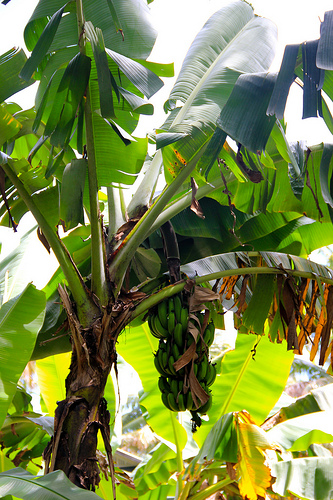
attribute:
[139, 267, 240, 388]
banana — hanging, bunch, here, bunched, bundled, present, unripe, stok, stock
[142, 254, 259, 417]
bananas — ripening, hanging, bunch, unripe, here, ready, green, growing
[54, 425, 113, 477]
trunk — thick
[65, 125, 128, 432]
tree — green, brown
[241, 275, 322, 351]
leaves — canopy, brown, drying, green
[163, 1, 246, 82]
sun — filtering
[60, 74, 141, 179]
leaf — palm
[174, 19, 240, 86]
sunlight — shining